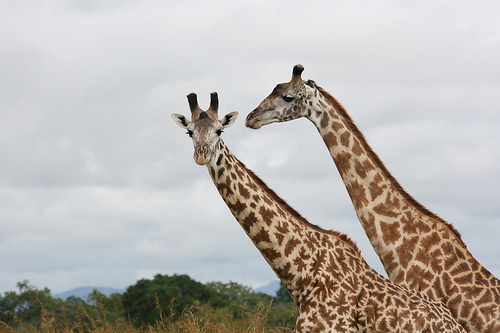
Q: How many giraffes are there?
A: Two.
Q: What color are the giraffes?
A: Spotted brown.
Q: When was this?
A: Daytime.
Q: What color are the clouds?
A: Grey.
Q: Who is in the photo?
A: No one.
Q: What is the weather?
A: Cloudy.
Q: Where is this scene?
A: Park.